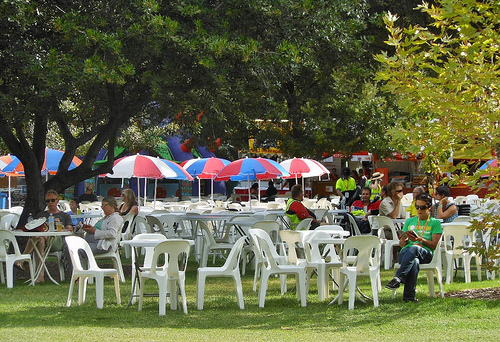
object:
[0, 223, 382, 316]
chairs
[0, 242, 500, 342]
lawn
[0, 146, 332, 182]
umbrellas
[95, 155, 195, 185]
umbrellas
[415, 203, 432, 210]
sunglasses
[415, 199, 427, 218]
face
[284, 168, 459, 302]
people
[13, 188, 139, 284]
people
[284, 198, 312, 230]
vest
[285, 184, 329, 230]
man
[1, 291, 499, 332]
shadows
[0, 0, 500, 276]
tree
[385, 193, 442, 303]
man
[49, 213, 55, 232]
bottle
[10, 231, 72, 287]
table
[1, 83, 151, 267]
trunk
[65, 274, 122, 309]
legs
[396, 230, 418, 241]
object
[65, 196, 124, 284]
woman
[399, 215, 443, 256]
shirt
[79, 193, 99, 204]
shirt